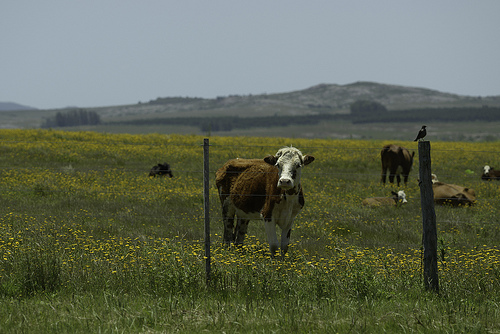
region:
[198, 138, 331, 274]
cow in the field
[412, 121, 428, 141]
bird on the post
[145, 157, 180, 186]
cow laying down in the field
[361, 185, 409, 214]
brown and white cow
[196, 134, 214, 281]
fence pole in the field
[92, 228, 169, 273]
flowers growing in the field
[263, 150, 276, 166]
ear of the cow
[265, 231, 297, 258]
legs of the cow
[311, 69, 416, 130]
hazy hills in the background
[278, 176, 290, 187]
nose of the cow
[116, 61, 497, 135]
mountains in the distance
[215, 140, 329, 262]
red and white cow standing in a field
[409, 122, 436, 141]
black bird perched on a post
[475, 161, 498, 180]
red and white cow laying in a field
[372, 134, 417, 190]
red cow standing in a field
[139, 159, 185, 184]
black cow laying in a field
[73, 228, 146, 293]
yellow flowers growing in a field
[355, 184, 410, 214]
red and white cow laying in a field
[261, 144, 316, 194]
head of a cow with white face and red ears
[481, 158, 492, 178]
white face of a cow in field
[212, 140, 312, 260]
brown and white cow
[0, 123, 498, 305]
field of yellow flowers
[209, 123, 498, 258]
cattle resting in field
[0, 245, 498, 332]
patch of green grass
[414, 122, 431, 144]
black bird on fence post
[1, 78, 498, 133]
dry hills in background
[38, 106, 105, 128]
patch of trees on hillside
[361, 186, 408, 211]
baby cow lying down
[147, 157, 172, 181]
black cow in distance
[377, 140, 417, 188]
cow facing away from camera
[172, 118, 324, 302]
a cow standing in the field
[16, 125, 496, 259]
a herd of cattle in a field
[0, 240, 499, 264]
yellow wild flowers in field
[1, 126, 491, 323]
a fence in front of cows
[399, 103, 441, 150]
a bird on post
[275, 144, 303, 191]
a cow's white face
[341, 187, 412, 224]
a brown and white cow laying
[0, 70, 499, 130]
grey rolling hills in back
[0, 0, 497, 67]
a bright clear sky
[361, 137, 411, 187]
the back of a cow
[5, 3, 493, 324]
cows in a meadow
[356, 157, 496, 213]
cattle lying down in meadow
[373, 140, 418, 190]
brown cow walking away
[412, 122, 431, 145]
black bird on post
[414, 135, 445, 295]
fence post by meadow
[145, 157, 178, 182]
cow lying down in meadow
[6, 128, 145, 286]
meadow with yellow flowers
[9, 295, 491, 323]
green grass by meadow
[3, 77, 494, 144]
hills behind the meadow